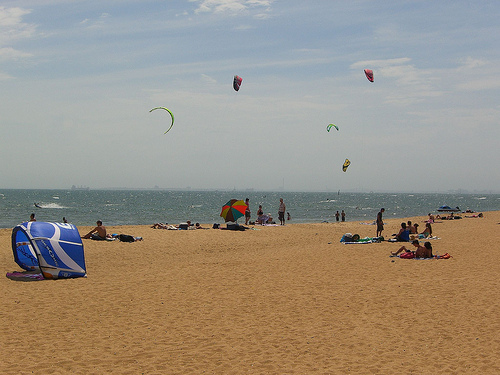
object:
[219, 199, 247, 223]
umbrella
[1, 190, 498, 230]
water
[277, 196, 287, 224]
people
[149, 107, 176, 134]
most sail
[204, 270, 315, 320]
sand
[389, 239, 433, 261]
couple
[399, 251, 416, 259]
red towel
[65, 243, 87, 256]
blue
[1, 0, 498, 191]
sky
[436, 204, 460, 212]
boat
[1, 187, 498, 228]
ocean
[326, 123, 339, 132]
kite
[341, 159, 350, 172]
kite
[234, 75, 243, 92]
kites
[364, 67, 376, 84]
kite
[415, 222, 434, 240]
person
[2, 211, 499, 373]
beach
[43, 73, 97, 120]
air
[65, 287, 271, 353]
ground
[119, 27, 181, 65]
air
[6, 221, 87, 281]
arch